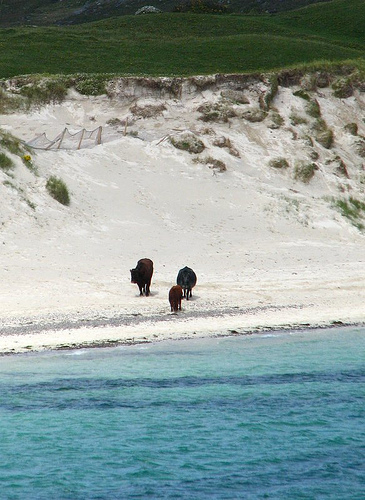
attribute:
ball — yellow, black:
[23, 153, 31, 161]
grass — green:
[5, 16, 363, 65]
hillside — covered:
[3, 7, 362, 356]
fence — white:
[27, 117, 176, 147]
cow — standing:
[165, 282, 182, 316]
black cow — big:
[173, 267, 195, 287]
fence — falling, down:
[23, 123, 134, 161]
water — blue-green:
[141, 425, 206, 455]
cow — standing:
[102, 244, 234, 340]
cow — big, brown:
[126, 252, 152, 291]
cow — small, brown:
[164, 280, 189, 312]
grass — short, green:
[0, 2, 364, 117]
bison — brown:
[128, 257, 154, 297]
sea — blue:
[4, 315, 364, 499]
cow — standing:
[126, 251, 161, 301]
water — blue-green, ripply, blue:
[1, 323, 360, 498]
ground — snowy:
[1, 59, 363, 354]